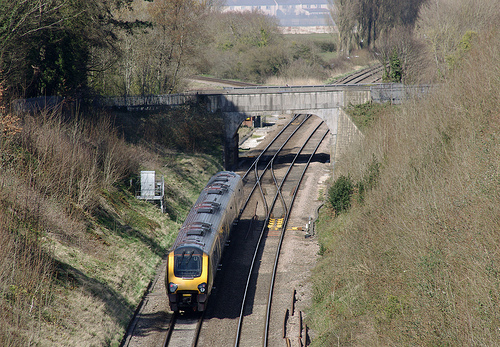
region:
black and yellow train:
[160, 170, 240, 307]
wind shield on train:
[174, 256, 199, 275]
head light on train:
[170, 285, 177, 290]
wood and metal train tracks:
[236, 121, 328, 345]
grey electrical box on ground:
[131, 167, 166, 212]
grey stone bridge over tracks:
[15, 83, 430, 165]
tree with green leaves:
[3, 2, 153, 107]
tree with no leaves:
[128, 1, 213, 91]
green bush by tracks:
[328, 175, 353, 215]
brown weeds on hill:
[316, 15, 498, 345]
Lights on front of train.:
[157, 277, 217, 300]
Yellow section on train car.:
[165, 253, 233, 315]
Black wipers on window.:
[173, 247, 207, 280]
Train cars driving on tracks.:
[166, 173, 235, 326]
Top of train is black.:
[186, 190, 220, 245]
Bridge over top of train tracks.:
[162, 81, 355, 134]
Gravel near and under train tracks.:
[193, 323, 227, 341]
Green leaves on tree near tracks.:
[330, 176, 352, 213]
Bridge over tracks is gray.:
[233, 78, 346, 147]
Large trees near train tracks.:
[17, 25, 99, 148]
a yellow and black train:
[168, 168, 245, 312]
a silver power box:
[135, 170, 166, 203]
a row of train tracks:
[232, 107, 330, 343]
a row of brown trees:
[0, 105, 124, 343]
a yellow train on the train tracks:
[131, 116, 322, 344]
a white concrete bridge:
[49, 89, 440, 116]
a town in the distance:
[221, 0, 337, 32]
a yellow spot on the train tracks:
[268, 218, 283, 227]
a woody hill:
[314, 0, 497, 341]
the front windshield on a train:
[174, 253, 200, 274]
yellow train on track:
[152, 169, 273, 294]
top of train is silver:
[155, 145, 263, 271]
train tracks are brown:
[227, 166, 291, 344]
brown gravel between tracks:
[207, 243, 282, 334]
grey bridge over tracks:
[169, 66, 395, 150]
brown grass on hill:
[340, 84, 488, 341]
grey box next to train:
[126, 166, 171, 208]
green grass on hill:
[108, 144, 210, 274]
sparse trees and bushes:
[10, 24, 99, 282]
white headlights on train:
[163, 269, 209, 298]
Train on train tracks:
[160, 140, 247, 312]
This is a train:
[157, 146, 247, 307]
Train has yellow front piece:
[158, 250, 221, 310]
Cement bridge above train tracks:
[68, 59, 461, 184]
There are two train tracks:
[115, 85, 383, 340]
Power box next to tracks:
[122, 168, 176, 223]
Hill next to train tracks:
[332, 13, 497, 343]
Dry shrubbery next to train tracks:
[0, 85, 82, 340]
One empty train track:
[255, 133, 300, 340]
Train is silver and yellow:
[160, 166, 260, 318]